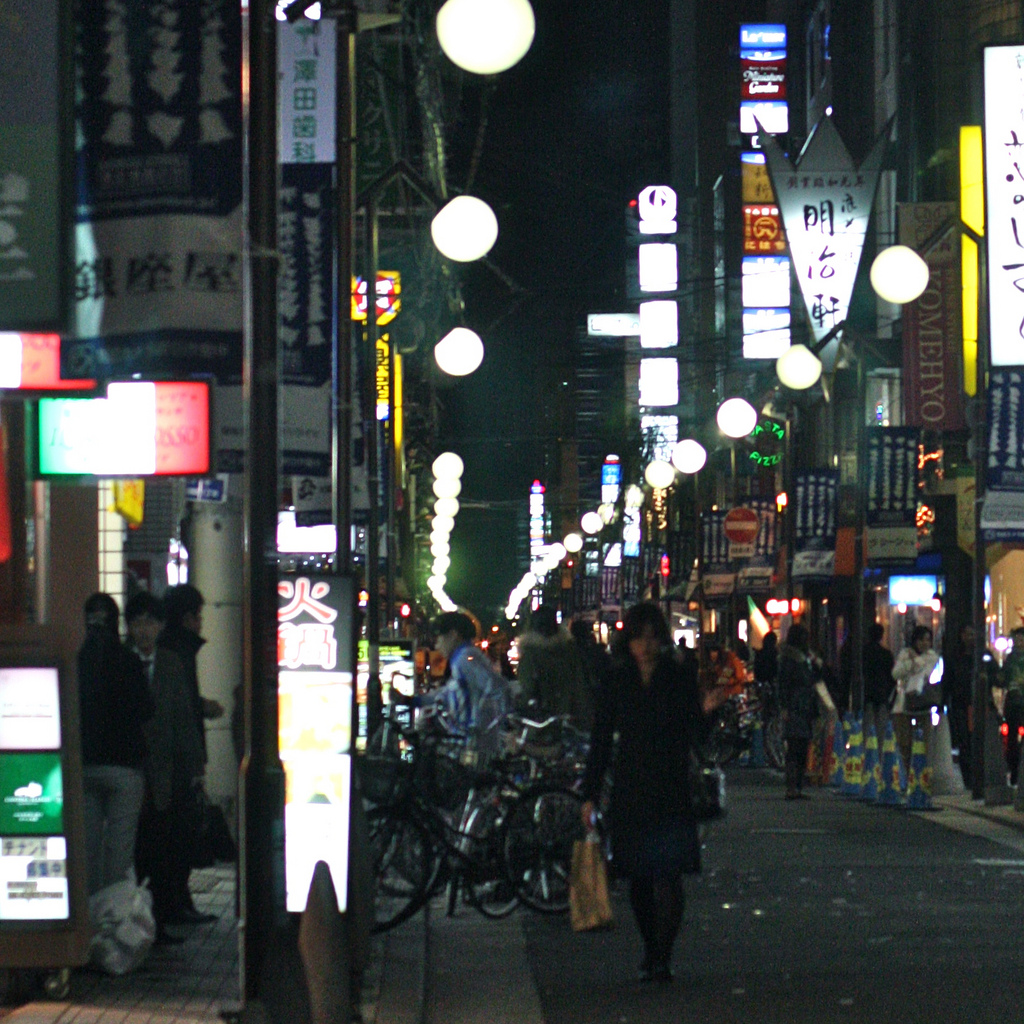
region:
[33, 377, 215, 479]
red green and white signboard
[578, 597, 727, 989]
woman walking in the street wearing black outfit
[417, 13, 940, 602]
a bunch of round lights in street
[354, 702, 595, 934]
bicycles parked in sidewalk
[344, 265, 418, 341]
yellow sign with red symbol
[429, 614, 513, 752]
person standing next to bicycles wearing light blue sweater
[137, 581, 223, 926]
person standing in sidewalk holding black suitcase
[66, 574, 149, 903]
person standing in sidewalk wearing jeans and dark cap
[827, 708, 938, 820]
blue and yellow traffic cones in street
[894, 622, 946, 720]
woman walking by sidewalk wearing white jacket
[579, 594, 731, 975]
woman talking on the phone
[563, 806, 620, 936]
brown paper bag woman is carrying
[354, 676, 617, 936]
bicycles on the street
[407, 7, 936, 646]
globe lights above the street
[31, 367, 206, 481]
red white and green lit sign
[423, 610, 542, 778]
man wearing blue shirt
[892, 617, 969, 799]
person wearing white shirt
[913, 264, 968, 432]
white lettering on red sign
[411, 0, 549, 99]
the light is white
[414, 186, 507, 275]
the light is white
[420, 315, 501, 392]
the light is white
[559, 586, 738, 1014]
the woman wears black clothes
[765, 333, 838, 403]
the light is white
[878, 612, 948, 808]
the girl wears a white top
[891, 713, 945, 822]
the cone is blue and green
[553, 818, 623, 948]
the paper bag is brown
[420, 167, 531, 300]
a view of lights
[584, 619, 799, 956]
a woman in road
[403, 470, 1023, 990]
a view of street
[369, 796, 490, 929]
a view of tire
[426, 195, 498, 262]
round streetlight is lit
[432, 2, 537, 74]
round streetlight is lit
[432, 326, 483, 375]
round streetlight is lit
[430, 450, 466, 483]
round streetlight is lit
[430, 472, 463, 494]
round streetlight is lit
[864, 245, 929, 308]
round streetlight is lit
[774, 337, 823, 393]
round streetlight is lit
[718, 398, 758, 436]
round streetlight is lit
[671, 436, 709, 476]
round streetlight is lit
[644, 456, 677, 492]
round streetlight is lit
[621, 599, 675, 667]
the head of a woman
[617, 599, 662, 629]
the hair of a woman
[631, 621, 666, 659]
the face of a woman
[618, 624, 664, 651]
the eyes of a woman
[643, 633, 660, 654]
the nose of a woman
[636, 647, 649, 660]
the mouth of a woman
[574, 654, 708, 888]
the jacket of a woman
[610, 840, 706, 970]
the legs of a woman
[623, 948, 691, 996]
the shoes of a woman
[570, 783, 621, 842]
the hand of a woman